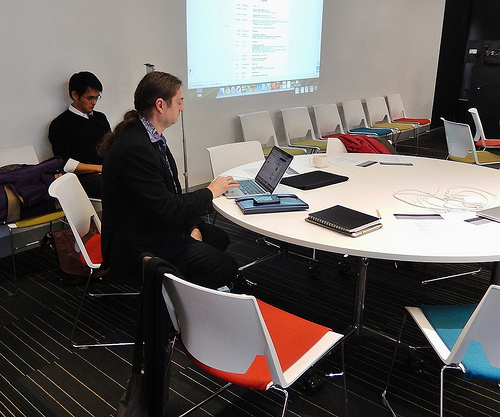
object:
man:
[101, 72, 241, 347]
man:
[48, 71, 116, 199]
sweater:
[48, 110, 113, 175]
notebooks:
[303, 204, 383, 238]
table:
[210, 152, 500, 265]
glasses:
[78, 95, 103, 101]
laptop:
[222, 144, 293, 199]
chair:
[141, 263, 345, 412]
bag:
[122, 256, 171, 415]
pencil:
[376, 208, 383, 220]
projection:
[186, 0, 323, 106]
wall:
[0, 2, 500, 258]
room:
[0, 0, 500, 417]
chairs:
[40, 169, 185, 351]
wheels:
[303, 377, 317, 390]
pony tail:
[101, 109, 140, 160]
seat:
[380, 294, 500, 417]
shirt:
[141, 113, 181, 192]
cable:
[393, 183, 500, 217]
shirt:
[66, 102, 95, 120]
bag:
[0, 154, 65, 223]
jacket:
[101, 114, 216, 277]